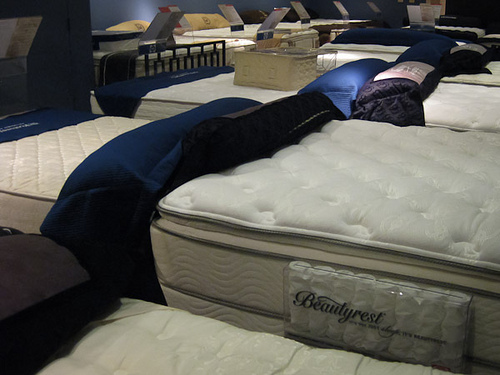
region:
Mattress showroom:
[0, 9, 487, 374]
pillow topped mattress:
[157, 101, 487, 278]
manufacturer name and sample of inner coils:
[285, 255, 481, 367]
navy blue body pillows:
[208, 52, 399, 117]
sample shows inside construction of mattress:
[231, 31, 344, 93]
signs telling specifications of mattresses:
[130, 4, 349, 43]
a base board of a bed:
[133, 37, 229, 85]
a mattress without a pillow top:
[2, 118, 169, 210]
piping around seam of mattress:
[2, 178, 60, 214]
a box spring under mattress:
[145, 281, 295, 333]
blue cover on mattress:
[0, 96, 107, 146]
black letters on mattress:
[293, 269, 383, 343]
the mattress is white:
[13, 98, 494, 337]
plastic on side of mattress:
[263, 248, 478, 365]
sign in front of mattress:
[255, 4, 290, 32]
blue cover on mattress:
[50, 82, 274, 247]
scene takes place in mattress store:
[0, 0, 483, 369]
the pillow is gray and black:
[0, 223, 123, 338]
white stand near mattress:
[230, 28, 318, 98]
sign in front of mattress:
[0, 7, 68, 70]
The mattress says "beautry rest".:
[285, 263, 465, 363]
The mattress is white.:
[265, 140, 495, 265]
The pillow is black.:
[191, 92, 341, 152]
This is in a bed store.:
[1, 16, 472, 363]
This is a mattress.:
[260, 117, 497, 277]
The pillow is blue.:
[311, 52, 383, 117]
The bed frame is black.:
[116, 37, 238, 71]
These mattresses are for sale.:
[114, 12, 495, 274]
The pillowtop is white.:
[151, 227, 282, 327]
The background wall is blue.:
[99, 3, 194, 29]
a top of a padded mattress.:
[1, 114, 498, 282]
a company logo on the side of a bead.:
[274, 239, 485, 367]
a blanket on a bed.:
[24, 70, 339, 308]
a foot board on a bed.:
[109, 31, 243, 110]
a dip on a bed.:
[341, 208, 386, 244]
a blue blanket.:
[279, 26, 396, 120]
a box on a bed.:
[227, 37, 358, 99]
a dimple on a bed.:
[307, 185, 362, 217]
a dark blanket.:
[32, 83, 346, 310]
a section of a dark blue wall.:
[93, 0, 164, 37]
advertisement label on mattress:
[283, 267, 475, 349]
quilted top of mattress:
[269, 112, 499, 279]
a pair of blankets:
[315, 39, 432, 128]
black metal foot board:
[101, 48, 235, 80]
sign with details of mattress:
[143, 5, 182, 50]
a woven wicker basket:
[232, 43, 321, 92]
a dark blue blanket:
[94, 128, 231, 180]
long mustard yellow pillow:
[177, 12, 234, 28]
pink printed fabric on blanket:
[388, 60, 431, 82]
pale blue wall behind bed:
[132, 4, 152, 21]